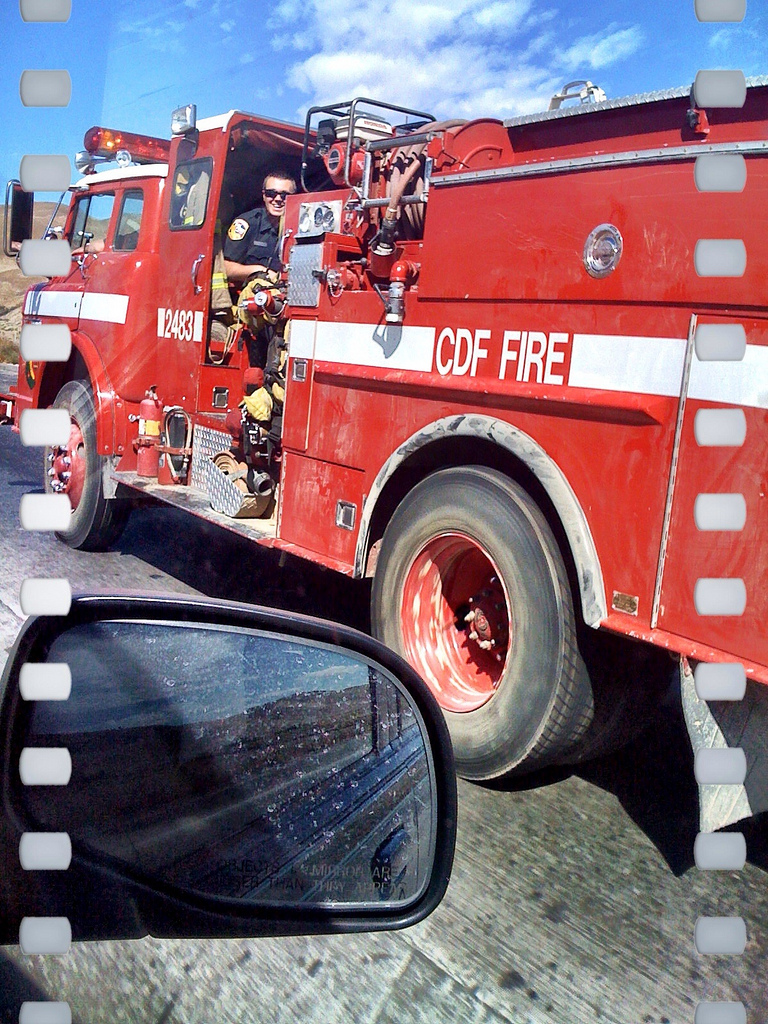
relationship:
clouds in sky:
[238, 6, 564, 119] [25, 12, 714, 144]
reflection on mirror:
[58, 671, 398, 904] [22, 587, 470, 950]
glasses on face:
[264, 188, 292, 200] [262, 171, 295, 215]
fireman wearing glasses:
[222, 169, 297, 302] [264, 188, 292, 200]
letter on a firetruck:
[543, 328, 583, 388] [26, 82, 736, 724]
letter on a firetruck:
[512, 330, 534, 385] [9, 53, 739, 578]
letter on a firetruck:
[182, 305, 195, 337] [25, 57, 702, 601]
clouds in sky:
[408, 6, 427, 46] [55, 29, 683, 100]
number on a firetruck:
[142, 299, 214, 328] [29, 213, 753, 740]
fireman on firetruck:
[222, 169, 297, 302] [4, 84, 766, 787]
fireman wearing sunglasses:
[217, 159, 299, 304] [263, 181, 300, 206]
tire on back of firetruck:
[366, 460, 600, 788] [4, 84, 766, 787]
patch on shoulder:
[228, 219, 247, 244] [224, 210, 264, 251]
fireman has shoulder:
[222, 169, 297, 302] [224, 210, 264, 251]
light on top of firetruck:
[82, 124, 171, 165] [4, 84, 766, 787]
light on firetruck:
[57, 75, 193, 169] [0, 60, 768, 791]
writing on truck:
[387, 280, 597, 401] [53, 57, 703, 795]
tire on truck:
[390, 490, 584, 762] [43, 55, 658, 647]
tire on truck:
[366, 460, 600, 788] [41, 51, 637, 1013]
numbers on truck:
[129, 277, 239, 388] [35, 86, 656, 795]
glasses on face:
[256, 170, 296, 202] [205, 159, 334, 374]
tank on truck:
[570, 175, 660, 297] [35, 86, 656, 795]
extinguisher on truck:
[119, 340, 226, 563] [78, 71, 688, 723]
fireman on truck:
[222, 169, 297, 302] [78, 71, 688, 723]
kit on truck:
[184, 370, 334, 624] [24, 78, 741, 756]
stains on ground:
[468, 916, 599, 1008] [48, 474, 708, 993]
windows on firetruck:
[48, 164, 196, 268] [0, 60, 768, 791]